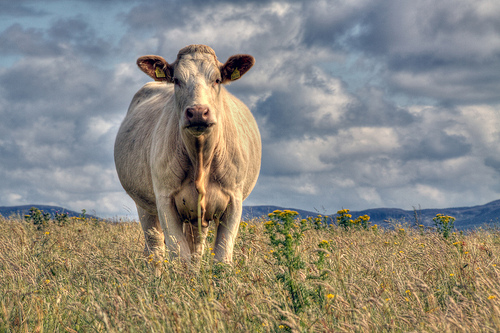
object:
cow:
[112, 44, 263, 267]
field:
[0, 206, 500, 330]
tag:
[154, 67, 165, 78]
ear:
[136, 54, 173, 84]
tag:
[231, 67, 241, 80]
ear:
[222, 55, 257, 82]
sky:
[0, 0, 499, 223]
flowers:
[326, 293, 335, 300]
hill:
[0, 199, 499, 235]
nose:
[185, 104, 210, 124]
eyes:
[215, 78, 222, 84]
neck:
[181, 121, 216, 170]